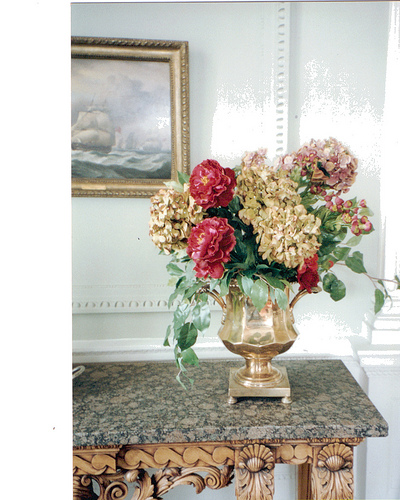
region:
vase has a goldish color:
[221, 291, 312, 379]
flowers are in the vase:
[199, 149, 288, 305]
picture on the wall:
[82, 21, 227, 193]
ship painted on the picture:
[78, 102, 124, 166]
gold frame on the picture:
[172, 86, 193, 149]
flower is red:
[183, 223, 233, 282]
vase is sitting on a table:
[223, 357, 295, 422]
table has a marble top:
[141, 390, 189, 422]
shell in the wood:
[322, 454, 344, 469]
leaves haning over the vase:
[138, 284, 206, 369]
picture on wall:
[64, 35, 190, 199]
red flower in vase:
[185, 160, 235, 210]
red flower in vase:
[185, 220, 235, 280]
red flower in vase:
[297, 258, 324, 290]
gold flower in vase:
[146, 184, 201, 251]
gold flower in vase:
[230, 158, 296, 214]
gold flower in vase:
[258, 213, 317, 262]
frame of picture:
[272, 16, 288, 157]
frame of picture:
[70, 292, 163, 309]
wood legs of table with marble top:
[77, 445, 351, 497]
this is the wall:
[197, 9, 249, 63]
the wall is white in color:
[219, 110, 265, 138]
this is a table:
[114, 364, 162, 437]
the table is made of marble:
[115, 371, 148, 424]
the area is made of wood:
[240, 456, 267, 496]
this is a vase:
[224, 289, 288, 404]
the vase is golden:
[244, 326, 273, 360]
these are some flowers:
[146, 177, 376, 252]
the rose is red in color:
[196, 227, 213, 249]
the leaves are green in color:
[168, 300, 198, 345]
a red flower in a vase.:
[181, 204, 242, 272]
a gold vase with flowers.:
[202, 240, 312, 417]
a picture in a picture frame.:
[74, 25, 210, 205]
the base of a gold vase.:
[220, 354, 308, 411]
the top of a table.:
[64, 355, 393, 441]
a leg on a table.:
[216, 421, 289, 497]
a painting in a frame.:
[67, 52, 176, 184]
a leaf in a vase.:
[318, 278, 355, 308]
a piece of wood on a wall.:
[342, 334, 394, 498]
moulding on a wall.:
[72, 280, 290, 323]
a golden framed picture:
[62, 32, 188, 196]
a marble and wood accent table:
[54, 353, 391, 498]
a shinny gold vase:
[196, 277, 321, 403]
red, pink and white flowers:
[156, 130, 397, 378]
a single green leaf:
[176, 320, 200, 350]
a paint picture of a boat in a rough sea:
[67, 55, 173, 184]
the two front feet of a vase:
[224, 390, 295, 406]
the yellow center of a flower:
[198, 174, 211, 184]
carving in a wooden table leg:
[234, 442, 275, 499]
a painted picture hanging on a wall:
[69, 33, 196, 198]